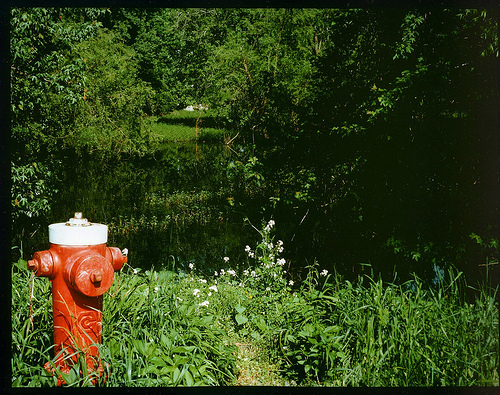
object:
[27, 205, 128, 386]
hydrant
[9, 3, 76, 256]
tree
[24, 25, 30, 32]
leaf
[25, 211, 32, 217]
leaf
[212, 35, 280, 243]
tree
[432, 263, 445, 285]
flower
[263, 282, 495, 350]
grass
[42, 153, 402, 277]
water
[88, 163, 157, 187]
reflection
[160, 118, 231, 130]
shadow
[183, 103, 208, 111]
building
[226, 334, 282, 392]
trail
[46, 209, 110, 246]
top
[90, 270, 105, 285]
lug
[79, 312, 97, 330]
letter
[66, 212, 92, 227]
lug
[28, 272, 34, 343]
chain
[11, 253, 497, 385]
area